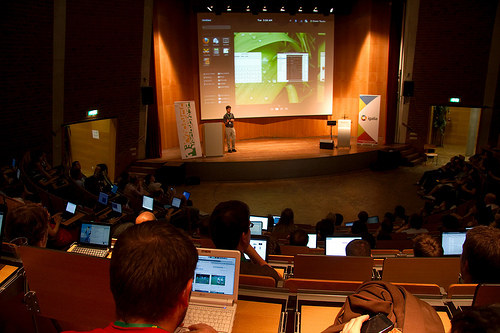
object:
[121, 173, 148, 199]
people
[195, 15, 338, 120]
presentation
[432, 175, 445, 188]
holding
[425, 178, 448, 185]
phone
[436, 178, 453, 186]
hand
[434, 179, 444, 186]
cell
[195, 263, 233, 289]
images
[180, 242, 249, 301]
computer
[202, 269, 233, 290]
displayed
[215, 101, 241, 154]
man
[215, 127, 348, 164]
stage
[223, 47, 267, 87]
text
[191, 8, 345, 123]
screen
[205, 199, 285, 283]
person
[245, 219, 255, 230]
glasses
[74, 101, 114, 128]
exit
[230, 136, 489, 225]
area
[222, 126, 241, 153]
article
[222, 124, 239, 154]
clothing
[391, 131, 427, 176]
steps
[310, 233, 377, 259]
computers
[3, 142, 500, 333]
classroom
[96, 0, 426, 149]
wall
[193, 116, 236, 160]
podium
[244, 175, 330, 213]
front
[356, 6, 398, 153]
sign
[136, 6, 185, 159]
side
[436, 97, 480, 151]
door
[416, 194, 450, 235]
stairs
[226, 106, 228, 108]
hair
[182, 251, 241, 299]
monitor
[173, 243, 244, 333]
laptop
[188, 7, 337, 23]
projector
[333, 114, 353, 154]
board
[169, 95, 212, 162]
standing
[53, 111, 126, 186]
entry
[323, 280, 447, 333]
jacket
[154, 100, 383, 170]
both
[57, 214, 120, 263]
laptops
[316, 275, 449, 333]
coat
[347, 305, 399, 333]
mobil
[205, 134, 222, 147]
white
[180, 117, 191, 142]
yellow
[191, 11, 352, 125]
green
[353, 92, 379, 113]
colored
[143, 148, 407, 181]
semi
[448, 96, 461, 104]
lit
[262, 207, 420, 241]
seating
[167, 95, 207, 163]
advertisement panel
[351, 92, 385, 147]
advertisement panel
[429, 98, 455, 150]
plant